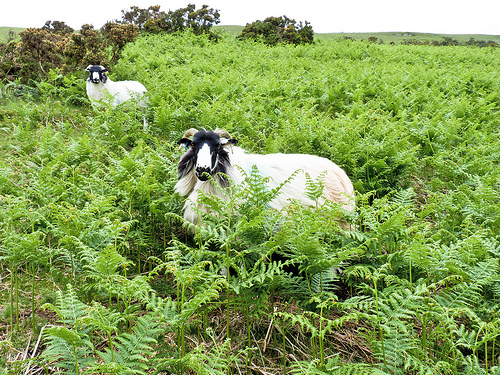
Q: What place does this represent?
A: It represents the field.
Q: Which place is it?
A: It is a field.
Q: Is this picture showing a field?
A: Yes, it is showing a field.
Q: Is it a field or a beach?
A: It is a field.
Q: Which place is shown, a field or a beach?
A: It is a field.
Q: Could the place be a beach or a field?
A: It is a field.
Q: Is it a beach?
A: No, it is a field.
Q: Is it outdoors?
A: Yes, it is outdoors.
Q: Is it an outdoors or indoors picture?
A: It is outdoors.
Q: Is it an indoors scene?
A: No, it is outdoors.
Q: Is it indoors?
A: No, it is outdoors.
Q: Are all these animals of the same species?
A: No, there are both sheep and goats.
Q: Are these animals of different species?
A: Yes, they are sheep and goats.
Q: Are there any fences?
A: No, there are no fences.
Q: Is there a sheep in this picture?
A: Yes, there is a sheep.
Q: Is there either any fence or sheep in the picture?
A: Yes, there is a sheep.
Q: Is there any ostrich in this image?
A: No, there are no ostriches.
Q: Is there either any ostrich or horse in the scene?
A: No, there are no ostriches or horses.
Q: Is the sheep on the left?
A: Yes, the sheep is on the left of the image.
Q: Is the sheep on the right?
A: No, the sheep is on the left of the image.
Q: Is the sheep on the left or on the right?
A: The sheep is on the left of the image.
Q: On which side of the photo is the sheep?
A: The sheep is on the left of the image.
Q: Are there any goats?
A: Yes, there is a goat.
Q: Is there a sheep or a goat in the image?
A: Yes, there is a goat.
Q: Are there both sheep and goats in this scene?
A: Yes, there are both a goat and a sheep.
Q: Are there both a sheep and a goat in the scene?
A: Yes, there are both a goat and a sheep.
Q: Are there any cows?
A: No, there are no cows.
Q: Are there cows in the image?
A: No, there are no cows.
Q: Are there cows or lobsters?
A: No, there are no cows or lobsters.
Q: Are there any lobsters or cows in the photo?
A: No, there are no cows or lobsters.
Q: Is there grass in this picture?
A: Yes, there is grass.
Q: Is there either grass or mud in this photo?
A: Yes, there is grass.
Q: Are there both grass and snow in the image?
A: No, there is grass but no snow.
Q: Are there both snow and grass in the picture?
A: No, there is grass but no snow.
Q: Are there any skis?
A: No, there are no skis.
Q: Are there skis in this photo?
A: No, there are no skis.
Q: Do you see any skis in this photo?
A: No, there are no skis.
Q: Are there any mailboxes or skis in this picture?
A: No, there are no skis or mailboxes.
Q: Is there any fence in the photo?
A: No, there are no fences.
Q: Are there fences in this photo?
A: No, there are no fences.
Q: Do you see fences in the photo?
A: No, there are no fences.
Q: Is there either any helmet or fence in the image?
A: No, there are no fences or helmets.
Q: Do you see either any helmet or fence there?
A: No, there are no fences or helmets.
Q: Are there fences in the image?
A: No, there are no fences.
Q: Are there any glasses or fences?
A: No, there are no fences or glasses.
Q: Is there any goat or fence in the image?
A: Yes, there is a goat.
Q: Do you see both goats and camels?
A: No, there is a goat but no camels.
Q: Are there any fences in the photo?
A: No, there are no fences.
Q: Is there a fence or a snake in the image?
A: No, there are no fences or snakes.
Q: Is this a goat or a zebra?
A: This is a goat.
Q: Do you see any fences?
A: No, there are no fences.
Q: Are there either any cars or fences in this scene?
A: No, there are no fences or cars.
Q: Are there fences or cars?
A: No, there are no fences or cars.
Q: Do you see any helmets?
A: No, there are no helmets.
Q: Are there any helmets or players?
A: No, there are no helmets or players.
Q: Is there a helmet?
A: No, there are no helmets.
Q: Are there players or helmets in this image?
A: No, there are no helmets or players.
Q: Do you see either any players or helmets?
A: No, there are no helmets or players.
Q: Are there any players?
A: No, there are no players.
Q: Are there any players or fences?
A: No, there are no players or fences.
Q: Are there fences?
A: No, there are no fences.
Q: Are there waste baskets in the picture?
A: No, there are no waste baskets.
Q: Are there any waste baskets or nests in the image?
A: No, there are no waste baskets or nests.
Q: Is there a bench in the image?
A: No, there are no benches.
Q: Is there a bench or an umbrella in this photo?
A: No, there are no benches or umbrellas.